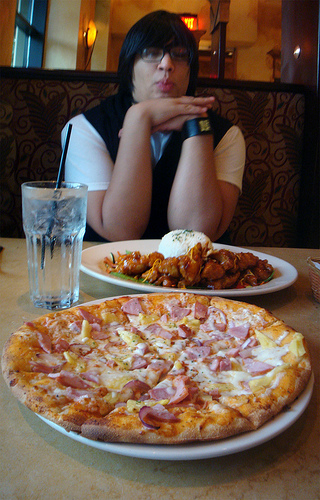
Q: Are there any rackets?
A: No, there are no rackets.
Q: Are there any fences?
A: No, there are no fences.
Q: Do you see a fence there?
A: No, there are no fences.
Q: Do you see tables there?
A: Yes, there is a table.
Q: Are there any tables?
A: Yes, there is a table.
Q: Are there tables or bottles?
A: Yes, there is a table.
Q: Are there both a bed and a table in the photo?
A: No, there is a table but no beds.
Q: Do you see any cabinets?
A: No, there are no cabinets.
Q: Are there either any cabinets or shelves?
A: No, there are no cabinets or shelves.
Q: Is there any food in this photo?
A: Yes, there is food.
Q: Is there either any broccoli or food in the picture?
A: Yes, there is food.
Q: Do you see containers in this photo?
A: No, there are no containers.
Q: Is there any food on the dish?
A: Yes, there is food on the dish.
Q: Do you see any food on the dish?
A: Yes, there is food on the dish.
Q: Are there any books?
A: No, there are no books.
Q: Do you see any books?
A: No, there are no books.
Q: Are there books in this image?
A: No, there are no books.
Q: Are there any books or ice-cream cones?
A: No, there are no books or ice-cream cones.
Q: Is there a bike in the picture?
A: No, there are no bikes.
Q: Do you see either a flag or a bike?
A: No, there are no bikes or flags.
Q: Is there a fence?
A: No, there are no fences.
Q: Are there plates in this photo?
A: Yes, there is a plate.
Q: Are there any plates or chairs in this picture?
A: Yes, there is a plate.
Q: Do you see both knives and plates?
A: No, there is a plate but no knives.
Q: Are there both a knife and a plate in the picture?
A: No, there is a plate but no knives.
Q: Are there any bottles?
A: No, there are no bottles.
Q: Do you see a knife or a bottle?
A: No, there are no bottles or knives.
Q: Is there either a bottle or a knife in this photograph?
A: No, there are no bottles or knives.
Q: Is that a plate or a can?
A: That is a plate.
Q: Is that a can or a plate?
A: That is a plate.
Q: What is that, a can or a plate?
A: That is a plate.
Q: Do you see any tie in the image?
A: Yes, there is a tie.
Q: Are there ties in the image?
A: Yes, there is a tie.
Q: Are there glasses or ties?
A: Yes, there is a tie.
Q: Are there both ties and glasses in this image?
A: Yes, there are both a tie and glasses.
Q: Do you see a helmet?
A: No, there are no helmets.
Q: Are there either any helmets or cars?
A: No, there are no helmets or cars.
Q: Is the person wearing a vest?
A: Yes, the person is wearing a vest.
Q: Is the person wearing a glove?
A: No, the person is wearing a vest.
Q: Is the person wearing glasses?
A: Yes, the person is wearing glasses.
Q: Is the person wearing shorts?
A: No, the person is wearing glasses.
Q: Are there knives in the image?
A: No, there are no knives.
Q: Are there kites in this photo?
A: No, there are no kites.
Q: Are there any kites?
A: No, there are no kites.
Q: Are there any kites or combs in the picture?
A: No, there are no kites or combs.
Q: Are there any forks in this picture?
A: No, there are no forks.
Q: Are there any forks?
A: No, there are no forks.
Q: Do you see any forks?
A: No, there are no forks.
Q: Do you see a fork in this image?
A: No, there are no forks.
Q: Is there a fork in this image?
A: No, there are no forks.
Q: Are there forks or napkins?
A: No, there are no forks or napkins.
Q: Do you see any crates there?
A: No, there are no crates.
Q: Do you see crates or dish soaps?
A: No, there are no crates or dish soaps.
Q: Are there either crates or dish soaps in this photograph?
A: No, there are no crates or dish soaps.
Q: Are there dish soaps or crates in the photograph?
A: No, there are no crates or dish soaps.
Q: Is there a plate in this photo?
A: Yes, there is a plate.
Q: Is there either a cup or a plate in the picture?
A: Yes, there is a plate.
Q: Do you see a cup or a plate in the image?
A: Yes, there is a plate.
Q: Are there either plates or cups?
A: Yes, there is a plate.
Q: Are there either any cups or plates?
A: Yes, there is a plate.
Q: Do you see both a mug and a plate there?
A: No, there is a plate but no mugs.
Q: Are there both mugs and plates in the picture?
A: No, there is a plate but no mugs.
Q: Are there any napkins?
A: No, there are no napkins.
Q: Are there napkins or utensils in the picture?
A: No, there are no napkins or utensils.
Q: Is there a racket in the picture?
A: No, there are no rackets.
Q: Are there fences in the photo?
A: No, there are no fences.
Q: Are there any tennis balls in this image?
A: No, there are no tennis balls.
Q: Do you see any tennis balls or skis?
A: No, there are no tennis balls or skis.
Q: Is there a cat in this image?
A: No, there are no cats.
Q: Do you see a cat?
A: No, there are no cats.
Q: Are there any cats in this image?
A: No, there are no cats.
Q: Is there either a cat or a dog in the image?
A: No, there are no cats or dogs.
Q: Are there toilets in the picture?
A: No, there are no toilets.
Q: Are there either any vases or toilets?
A: No, there are no toilets or vases.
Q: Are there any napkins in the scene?
A: No, there are no napkins.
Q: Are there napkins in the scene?
A: No, there are no napkins.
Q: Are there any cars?
A: No, there are no cars.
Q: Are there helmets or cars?
A: No, there are no cars or helmets.